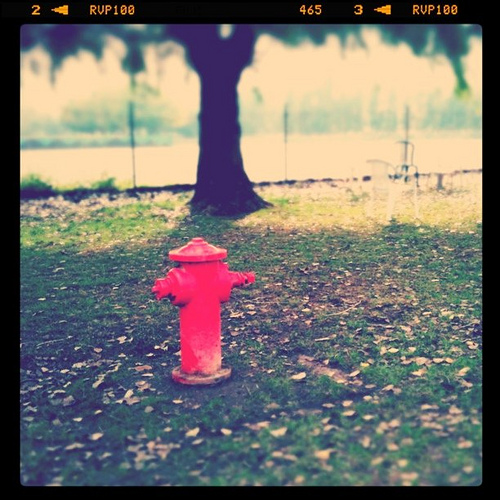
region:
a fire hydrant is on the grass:
[157, 238, 254, 386]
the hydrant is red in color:
[149, 234, 254, 387]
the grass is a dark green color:
[16, 195, 479, 485]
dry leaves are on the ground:
[15, 195, 485, 485]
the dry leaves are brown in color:
[25, 197, 481, 483]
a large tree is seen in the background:
[10, 31, 476, 207]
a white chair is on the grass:
[362, 153, 420, 223]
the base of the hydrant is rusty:
[170, 360, 231, 386]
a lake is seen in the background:
[20, 121, 490, 191]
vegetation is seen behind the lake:
[23, 90, 496, 144]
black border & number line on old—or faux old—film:
[22, 0, 463, 17]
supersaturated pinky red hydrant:
[145, 232, 260, 389]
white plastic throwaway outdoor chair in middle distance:
[360, 152, 425, 227]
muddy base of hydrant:
[170, 360, 233, 386]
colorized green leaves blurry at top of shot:
[20, 25, 480, 100]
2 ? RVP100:
[25, 3, 136, 18]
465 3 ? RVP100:
[297, 3, 464, 20]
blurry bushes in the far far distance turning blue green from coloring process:
[21, 77, 481, 153]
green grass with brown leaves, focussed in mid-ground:
[356, 320, 478, 481]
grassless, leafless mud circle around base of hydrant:
[152, 350, 255, 405]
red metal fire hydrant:
[151, 223, 259, 400]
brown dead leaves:
[15, 168, 498, 484]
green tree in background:
[22, 0, 467, 239]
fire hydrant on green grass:
[148, 236, 261, 390]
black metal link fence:
[23, 72, 485, 194]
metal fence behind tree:
[21, 72, 478, 197]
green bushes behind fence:
[23, 22, 481, 198]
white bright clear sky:
[23, 30, 498, 180]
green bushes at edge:
[22, 166, 122, 202]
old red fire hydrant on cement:
[148, 227, 261, 391]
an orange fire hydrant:
[31, 199, 384, 460]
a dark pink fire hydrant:
[119, 213, 291, 400]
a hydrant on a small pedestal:
[132, 191, 280, 418]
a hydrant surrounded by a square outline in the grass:
[28, 215, 380, 465]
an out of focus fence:
[25, 79, 497, 198]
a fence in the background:
[51, 78, 466, 213]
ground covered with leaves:
[19, 187, 475, 498]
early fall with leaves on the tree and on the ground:
[9, 15, 472, 393]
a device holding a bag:
[352, 118, 434, 255]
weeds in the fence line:
[14, 151, 137, 208]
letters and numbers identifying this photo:
[25, 0, 491, 23]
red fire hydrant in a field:
[153, 237, 248, 386]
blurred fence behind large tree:
[0, 103, 485, 188]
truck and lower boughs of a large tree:
[17, 16, 480, 213]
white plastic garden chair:
[357, 155, 431, 220]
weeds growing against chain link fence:
[21, 173, 130, 200]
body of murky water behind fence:
[15, 127, 484, 174]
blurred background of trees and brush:
[19, 88, 479, 146]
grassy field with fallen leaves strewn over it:
[24, 185, 484, 487]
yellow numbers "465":
[297, 3, 330, 18]